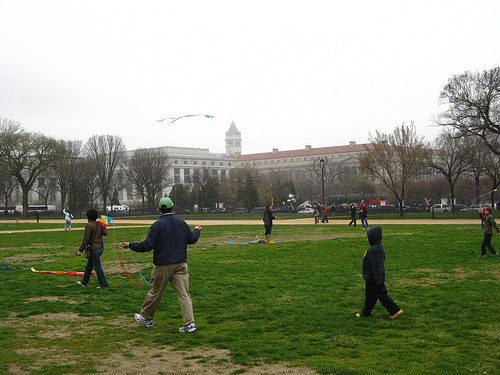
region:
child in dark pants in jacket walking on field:
[355, 225, 400, 320]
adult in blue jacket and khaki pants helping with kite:
[120, 197, 201, 333]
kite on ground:
[29, 266, 92, 275]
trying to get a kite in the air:
[60, 207, 113, 225]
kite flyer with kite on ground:
[227, 201, 278, 244]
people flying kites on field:
[25, 110, 497, 338]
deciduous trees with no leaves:
[357, 65, 493, 211]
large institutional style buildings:
[0, 120, 497, 206]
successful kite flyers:
[155, 112, 326, 222]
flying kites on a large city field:
[1, 110, 498, 369]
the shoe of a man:
[175, 321, 195, 333]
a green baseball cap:
[155, 194, 173, 208]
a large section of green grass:
[2, 223, 498, 373]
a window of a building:
[172, 165, 183, 184]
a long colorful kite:
[151, 103, 219, 125]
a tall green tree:
[357, 123, 444, 219]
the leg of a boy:
[480, 231, 489, 254]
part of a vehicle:
[248, 204, 265, 214]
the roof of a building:
[226, 145, 380, 160]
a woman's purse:
[80, 221, 99, 259]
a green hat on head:
[152, 197, 189, 217]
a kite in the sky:
[133, 94, 231, 144]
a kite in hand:
[58, 190, 136, 305]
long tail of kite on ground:
[13, 248, 140, 297]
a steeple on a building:
[214, 111, 244, 172]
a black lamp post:
[308, 139, 348, 236]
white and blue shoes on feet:
[123, 305, 200, 343]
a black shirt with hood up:
[356, 220, 398, 293]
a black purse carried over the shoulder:
[66, 208, 118, 265]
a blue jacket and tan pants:
[113, 205, 223, 358]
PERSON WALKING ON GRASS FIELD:
[141, 180, 193, 355]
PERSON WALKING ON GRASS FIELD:
[91, 197, 100, 309]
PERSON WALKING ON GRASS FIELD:
[247, 190, 280, 252]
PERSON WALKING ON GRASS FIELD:
[369, 202, 386, 312]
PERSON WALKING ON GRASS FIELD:
[470, 220, 487, 259]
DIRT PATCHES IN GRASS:
[122, 347, 152, 369]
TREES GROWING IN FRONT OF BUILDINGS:
[4, 137, 146, 217]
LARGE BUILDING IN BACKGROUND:
[56, 141, 468, 268]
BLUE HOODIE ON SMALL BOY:
[359, 218, 416, 308]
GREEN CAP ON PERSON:
[161, 198, 176, 214]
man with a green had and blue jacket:
[135, 200, 198, 332]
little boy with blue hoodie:
[350, 222, 401, 318]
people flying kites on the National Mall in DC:
[60, 205, 496, 325]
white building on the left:
[10, 150, 236, 210]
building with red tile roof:
[245, 145, 457, 195]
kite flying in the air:
[164, 112, 214, 122]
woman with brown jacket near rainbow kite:
[77, 210, 116, 285]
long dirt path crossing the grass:
[18, 217, 498, 224]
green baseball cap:
[155, 197, 172, 208]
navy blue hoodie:
[360, 223, 385, 284]